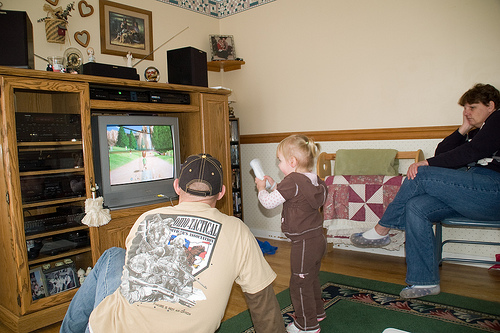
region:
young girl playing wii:
[238, 125, 343, 332]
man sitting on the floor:
[27, 143, 297, 330]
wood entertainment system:
[5, 55, 247, 332]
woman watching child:
[315, 81, 497, 304]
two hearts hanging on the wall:
[67, 0, 107, 55]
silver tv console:
[85, 96, 200, 221]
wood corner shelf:
[196, 15, 246, 76]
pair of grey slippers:
[340, 205, 445, 305]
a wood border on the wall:
[235, 110, 490, 155]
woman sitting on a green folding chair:
[355, 81, 499, 305]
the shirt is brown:
[227, 248, 239, 268]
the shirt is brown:
[237, 269, 252, 286]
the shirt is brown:
[232, 257, 255, 282]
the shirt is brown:
[239, 265, 259, 283]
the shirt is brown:
[243, 248, 255, 274]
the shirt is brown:
[227, 252, 247, 277]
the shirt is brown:
[229, 241, 241, 263]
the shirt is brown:
[218, 253, 233, 274]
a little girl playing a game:
[230, 110, 346, 320]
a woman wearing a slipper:
[392, 270, 463, 326]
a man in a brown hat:
[168, 145, 233, 225]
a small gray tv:
[84, 102, 210, 223]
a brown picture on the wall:
[89, 1, 165, 61]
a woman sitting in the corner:
[369, 78, 497, 267]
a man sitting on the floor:
[27, 144, 287, 331]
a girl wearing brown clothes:
[262, 161, 350, 331]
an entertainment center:
[4, 68, 250, 315]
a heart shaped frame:
[67, 17, 110, 59]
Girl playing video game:
[248, 132, 328, 331]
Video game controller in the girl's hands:
[248, 156, 274, 188]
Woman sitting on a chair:
[351, 82, 498, 297]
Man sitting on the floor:
[60, 152, 284, 331]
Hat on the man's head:
[177, 153, 224, 195]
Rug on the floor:
[211, 270, 496, 331]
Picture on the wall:
[99, 0, 155, 60]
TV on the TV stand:
[92, 112, 182, 209]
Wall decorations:
[37, 1, 94, 48]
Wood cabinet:
[5, 66, 247, 331]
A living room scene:
[14, 28, 491, 302]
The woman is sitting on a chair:
[351, 69, 498, 299]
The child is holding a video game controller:
[245, 130, 348, 331]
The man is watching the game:
[91, 109, 255, 325]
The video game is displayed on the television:
[91, 108, 182, 208]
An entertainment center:
[0, 68, 182, 313]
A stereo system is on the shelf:
[16, 104, 82, 176]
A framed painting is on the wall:
[91, 0, 159, 58]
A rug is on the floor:
[327, 258, 392, 317]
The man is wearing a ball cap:
[171, 143, 232, 208]